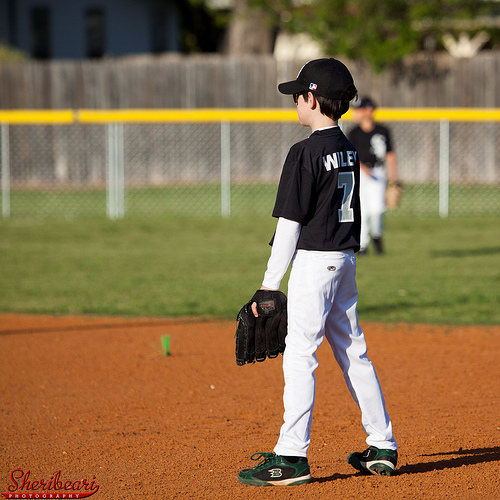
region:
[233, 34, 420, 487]
boy wearing black shirt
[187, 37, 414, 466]
boy wearing black baseball mitt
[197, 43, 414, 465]
boy wearing white pants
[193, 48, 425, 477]
boy playing baseball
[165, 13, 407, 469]
boy wearing black sunglasses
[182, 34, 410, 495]
boy wearing green and black cleats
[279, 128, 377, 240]
name and number on shirt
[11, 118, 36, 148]
metal square on fence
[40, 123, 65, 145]
metal square on fence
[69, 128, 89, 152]
metal square on fence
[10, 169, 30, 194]
metal square on fence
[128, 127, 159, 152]
metal square on fence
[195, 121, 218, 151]
metal square on fence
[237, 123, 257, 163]
metal square on fence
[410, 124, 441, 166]
metal square on fence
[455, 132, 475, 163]
metal square on fence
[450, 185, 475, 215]
metal square on fence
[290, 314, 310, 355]
white pants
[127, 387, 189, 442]
the turf is brown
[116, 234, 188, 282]
the grass is low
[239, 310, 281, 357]
a black baseball glove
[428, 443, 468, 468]
a shadow on the field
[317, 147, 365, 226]
writing on the jersey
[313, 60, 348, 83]
boy is wearing a hat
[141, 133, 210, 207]
a small fence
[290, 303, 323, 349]
the boy is wearing pants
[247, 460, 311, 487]
boy is wearing black shoes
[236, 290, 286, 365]
a black baseball glove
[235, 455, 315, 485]
a boy's tennis shoe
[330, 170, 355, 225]
the boy's player number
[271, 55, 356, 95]
a black baseball cap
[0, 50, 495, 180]
part of a wooden fence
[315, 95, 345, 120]
part of a boy's black hair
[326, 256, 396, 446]
the leg of a boy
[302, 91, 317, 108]
the ear of a boy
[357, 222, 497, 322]
a section of green grass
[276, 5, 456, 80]
green tree leaves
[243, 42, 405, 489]
This is a boy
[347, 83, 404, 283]
This is a boy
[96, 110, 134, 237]
This is a pole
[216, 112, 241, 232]
This is a pole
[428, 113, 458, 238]
This is a pole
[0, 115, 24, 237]
This is a pole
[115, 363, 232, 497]
Section of the field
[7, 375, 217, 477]
Section of the field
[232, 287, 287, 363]
the black glove held by the boy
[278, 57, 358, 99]
the hat on the boy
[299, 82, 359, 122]
the hair on the boy